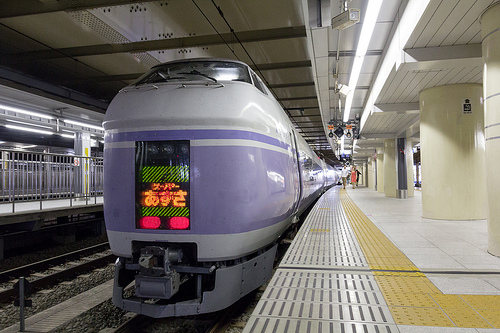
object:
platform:
[308, 184, 422, 332]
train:
[96, 55, 337, 320]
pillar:
[418, 87, 487, 219]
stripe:
[189, 137, 292, 156]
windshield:
[133, 59, 251, 83]